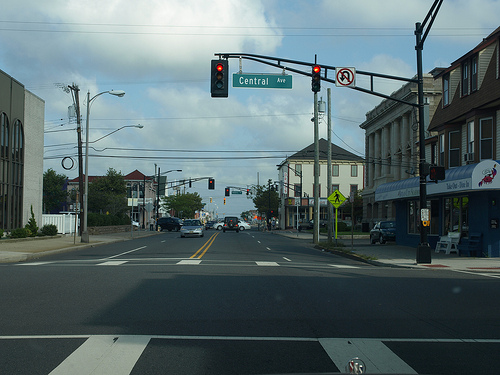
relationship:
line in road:
[4, 330, 499, 349] [1, 215, 499, 374]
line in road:
[98, 225, 151, 265] [1, 215, 499, 374]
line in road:
[239, 226, 294, 266] [1, 215, 499, 374]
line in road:
[188, 226, 221, 261] [1, 215, 499, 374]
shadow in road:
[96, 273, 497, 374] [1, 215, 499, 374]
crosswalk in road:
[8, 258, 405, 273] [1, 215, 499, 374]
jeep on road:
[223, 214, 241, 232] [1, 215, 499, 374]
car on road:
[181, 218, 207, 238] [1, 215, 499, 374]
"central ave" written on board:
[236, 74, 291, 84] [225, 66, 311, 96]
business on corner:
[427, 0, 499, 257] [374, 253, 499, 274]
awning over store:
[373, 157, 499, 203] [391, 25, 494, 248]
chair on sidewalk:
[437, 226, 459, 264] [405, 229, 490, 304]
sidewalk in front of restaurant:
[405, 229, 490, 304] [435, 158, 487, 253]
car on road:
[210, 219, 253, 230] [1, 215, 499, 374]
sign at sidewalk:
[324, 175, 343, 236] [16, 237, 63, 244]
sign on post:
[333, 62, 358, 89] [207, 2, 454, 266]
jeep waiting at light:
[222, 216, 240, 233] [164, 156, 286, 194]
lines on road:
[133, 252, 310, 374] [1, 215, 499, 374]